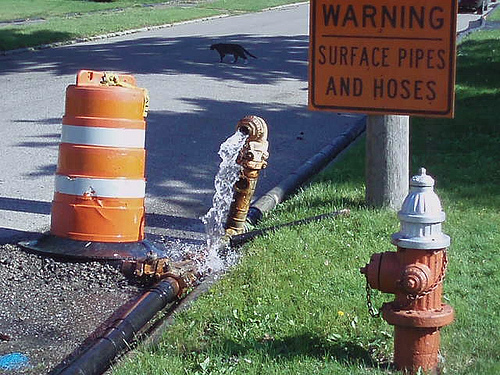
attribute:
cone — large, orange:
[20, 67, 155, 256]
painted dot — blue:
[0, 350, 32, 372]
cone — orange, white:
[18, 61, 172, 271]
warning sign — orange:
[305, 0, 457, 118]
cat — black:
[208, 36, 258, 67]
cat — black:
[202, 34, 250, 66]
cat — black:
[208, 43, 253, 64]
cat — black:
[205, 40, 257, 65]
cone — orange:
[42, 50, 173, 254]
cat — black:
[206, 36, 265, 71]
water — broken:
[50, 112, 276, 334]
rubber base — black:
[15, 230, 157, 261]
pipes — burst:
[137, 110, 301, 300]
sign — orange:
[286, 4, 466, 111]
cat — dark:
[192, 33, 264, 80]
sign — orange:
[312, 7, 454, 114]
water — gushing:
[198, 126, 248, 272]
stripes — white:
[47, 123, 151, 197]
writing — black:
[315, 3, 452, 103]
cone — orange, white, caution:
[17, 68, 165, 259]